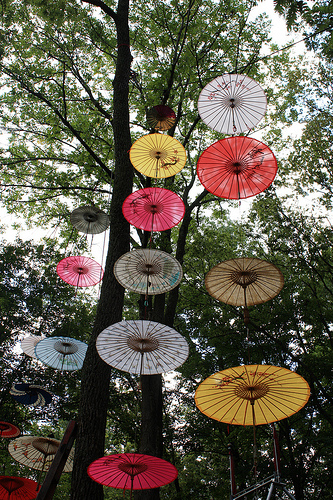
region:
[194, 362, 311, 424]
Yellow circular umbrella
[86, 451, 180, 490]
Pink circular umbrella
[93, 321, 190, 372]
White circular umbrella above pink umbrella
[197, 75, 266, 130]
White umbrella above red umbrella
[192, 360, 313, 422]
Yellow umbrella below brown umbrella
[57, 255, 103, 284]
Pink umbrella above blue umbrella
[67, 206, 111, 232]
Gray umbrella above pink umbrella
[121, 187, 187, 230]
Pink umbrella by tree trunk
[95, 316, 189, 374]
White umbrella by tree trunk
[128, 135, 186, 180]
Yellow umbrella by tree trunk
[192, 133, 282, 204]
The red umbrella furthest right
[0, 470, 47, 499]
The lowest of the red umbrellas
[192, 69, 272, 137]
The highest white umbrella to the right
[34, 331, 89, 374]
The only blue umbrella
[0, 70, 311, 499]
The umbrellas in the trees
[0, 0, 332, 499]
The trees the umbrellas are in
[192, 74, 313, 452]
The row of umbrellas on the right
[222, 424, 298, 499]
The structure made of two by fours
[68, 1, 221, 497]
The two tree trunks rising next to each other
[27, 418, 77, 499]
The plank leaning against the tree trunk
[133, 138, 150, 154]
part of an umbrella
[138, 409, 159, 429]
stem of a tree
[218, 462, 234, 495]
part of a metal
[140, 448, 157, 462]
edge of an umbrella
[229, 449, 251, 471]
part of a stand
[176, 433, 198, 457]
part of a branch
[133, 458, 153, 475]
part of an umbrella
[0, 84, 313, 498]
beautiful paper umbrellas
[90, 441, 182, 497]
this one is red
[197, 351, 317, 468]
this umbrella has designs on it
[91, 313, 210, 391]
the umbrella has a delicate pattern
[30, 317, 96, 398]
the blue umbrella is pretty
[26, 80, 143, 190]
the tree is very tall & green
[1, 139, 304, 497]
all the umbrellas appear to be decorations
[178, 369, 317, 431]
the umbrellas have a delicate structure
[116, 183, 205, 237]
this is the most beautiful of umbrella or all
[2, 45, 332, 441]
many japanese umbrellas dot the tree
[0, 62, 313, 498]
small umbrellas hanging from a tree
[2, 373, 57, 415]
A blue and white spiral umbrella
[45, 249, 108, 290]
A pink umbrella with the sun shining through it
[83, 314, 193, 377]
A white umbrella with small designs on it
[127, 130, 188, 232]
two umbrellas with cherry blossom designs on them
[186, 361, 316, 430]
A yellow umbrella with a cherry blossom design on it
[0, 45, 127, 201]
tall green trees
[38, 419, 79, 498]
A ladder propped against a tree trunk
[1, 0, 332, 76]
clouds through the tree tops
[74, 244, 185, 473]
two trees growing close together